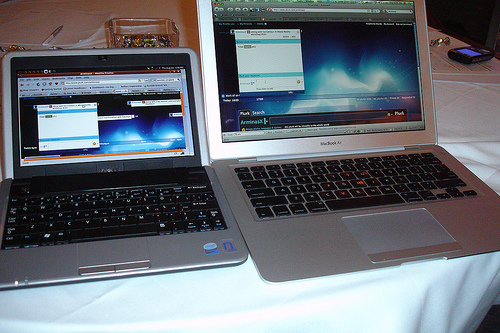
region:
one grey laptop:
[200, 10, 496, 273]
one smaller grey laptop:
[1, 61, 240, 277]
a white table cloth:
[4, 282, 456, 331]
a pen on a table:
[12, 16, 82, 59]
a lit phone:
[441, 35, 495, 80]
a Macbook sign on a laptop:
[307, 120, 374, 176]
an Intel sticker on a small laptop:
[199, 242, 228, 267]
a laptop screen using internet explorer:
[212, 12, 437, 133]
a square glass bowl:
[105, 9, 205, 54]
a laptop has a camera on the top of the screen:
[96, 48, 120, 70]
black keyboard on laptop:
[72, 191, 167, 266]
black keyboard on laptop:
[70, 152, 157, 242]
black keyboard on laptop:
[22, 168, 127, 259]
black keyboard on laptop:
[54, 194, 109, 234]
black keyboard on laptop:
[84, 181, 158, 228]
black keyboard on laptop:
[47, 164, 134, 202]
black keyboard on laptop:
[45, 187, 207, 281]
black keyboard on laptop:
[72, 197, 113, 221]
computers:
[3, 2, 499, 282]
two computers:
[3, 1, 499, 291]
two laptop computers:
[3, 1, 499, 292]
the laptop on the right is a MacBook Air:
[197, 0, 499, 296]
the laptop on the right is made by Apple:
[197, 2, 497, 292]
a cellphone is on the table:
[445, 36, 499, 64]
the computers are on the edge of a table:
[3, 0, 498, 304]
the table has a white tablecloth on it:
[12, 2, 497, 330]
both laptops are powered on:
[5, 1, 497, 294]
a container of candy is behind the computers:
[100, 15, 193, 56]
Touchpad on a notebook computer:
[337, 206, 469, 242]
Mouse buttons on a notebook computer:
[366, 238, 467, 265]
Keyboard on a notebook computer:
[232, 151, 479, 206]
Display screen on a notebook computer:
[210, 1, 434, 135]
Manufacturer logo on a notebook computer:
[318, 137, 344, 149]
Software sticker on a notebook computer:
[203, 238, 219, 263]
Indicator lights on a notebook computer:
[10, 273, 34, 291]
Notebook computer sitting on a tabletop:
[0, 47, 265, 287]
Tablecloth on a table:
[170, 283, 486, 326]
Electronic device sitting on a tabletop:
[450, 33, 496, 73]